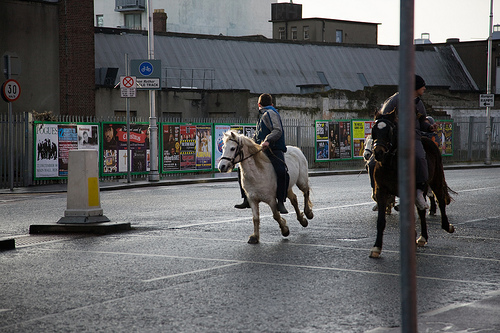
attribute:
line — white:
[140, 253, 260, 296]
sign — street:
[114, 52, 189, 105]